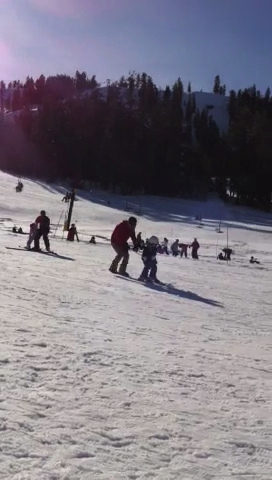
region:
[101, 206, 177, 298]
adult and child skiing on snow covered hill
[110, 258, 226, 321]
shadow of skiing adult and child on surface of snow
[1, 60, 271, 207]
tall evergreen trees bordering snow covered hill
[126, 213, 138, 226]
balck hat on person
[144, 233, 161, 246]
white hat on child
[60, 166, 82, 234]
upright pole in snow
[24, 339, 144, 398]
blemish marks in snow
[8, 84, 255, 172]
snow covered rock formation between trees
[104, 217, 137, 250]
red coat on person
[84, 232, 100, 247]
object on snow covered ground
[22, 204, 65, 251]
this is a person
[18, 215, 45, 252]
this is a person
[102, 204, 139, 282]
this is a person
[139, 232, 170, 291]
this is a person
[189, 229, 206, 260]
this is a person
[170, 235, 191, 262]
this is a person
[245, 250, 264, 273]
this is a person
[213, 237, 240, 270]
this is a person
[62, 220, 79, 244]
this is a person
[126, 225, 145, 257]
this is a person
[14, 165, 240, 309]
group of people in snow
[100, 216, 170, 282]
person bending down near child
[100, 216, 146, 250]
person wearing red jacket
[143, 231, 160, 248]
child wearing white helmet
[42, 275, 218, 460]
multiple tracks in snow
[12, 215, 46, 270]
child standing on skis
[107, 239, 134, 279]
person wearing brown pants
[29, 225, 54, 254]
man standing with legs apart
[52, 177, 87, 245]
pole in snow in background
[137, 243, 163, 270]
child wearing dark coat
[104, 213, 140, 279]
person in red coat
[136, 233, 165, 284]
child in white hat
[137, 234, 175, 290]
small child on skis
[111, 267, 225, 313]
shadows cast in the snow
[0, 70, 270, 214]
trees on snowy hillside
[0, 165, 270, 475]
snowy hillside with many skiers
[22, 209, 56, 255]
man and child together on hillside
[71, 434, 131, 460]
deep footprints in the snow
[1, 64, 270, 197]
snowy hillside in background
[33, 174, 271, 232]
shadows of trees cast on ground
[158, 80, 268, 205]
lights on a building at a ski resort.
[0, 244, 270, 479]
the snow has many prints in it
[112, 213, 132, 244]
a person in a red parka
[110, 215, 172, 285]
adult teaches child to ski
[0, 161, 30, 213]
peoplw ride the chairlift up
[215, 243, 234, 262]
adult helps a child who has fallen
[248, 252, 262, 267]
a person sitting in the snow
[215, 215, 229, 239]
returning chair on the skilift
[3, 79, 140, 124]
glare of the sun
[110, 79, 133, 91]
chimney on the roof behind the tree top